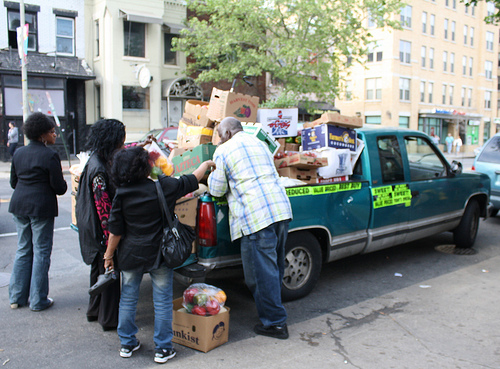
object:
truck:
[67, 123, 491, 304]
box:
[203, 87, 260, 123]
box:
[254, 107, 299, 139]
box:
[302, 111, 364, 131]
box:
[297, 120, 359, 155]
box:
[272, 150, 327, 169]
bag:
[180, 281, 227, 316]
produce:
[189, 293, 209, 309]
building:
[186, 0, 267, 105]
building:
[0, 0, 97, 161]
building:
[266, 0, 498, 160]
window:
[404, 17, 411, 29]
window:
[398, 50, 405, 62]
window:
[397, 75, 405, 90]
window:
[374, 89, 383, 101]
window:
[427, 79, 435, 94]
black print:
[284, 186, 309, 198]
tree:
[170, 0, 406, 114]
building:
[295, 99, 341, 122]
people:
[451, 134, 463, 156]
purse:
[149, 175, 194, 268]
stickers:
[309, 180, 361, 195]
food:
[199, 125, 213, 139]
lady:
[6, 110, 68, 314]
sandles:
[86, 268, 118, 294]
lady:
[101, 144, 216, 365]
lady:
[73, 114, 125, 331]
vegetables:
[158, 161, 176, 177]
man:
[206, 115, 296, 342]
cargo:
[168, 142, 220, 178]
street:
[0, 151, 499, 369]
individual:
[4, 119, 19, 158]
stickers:
[390, 182, 412, 209]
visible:
[182, 280, 230, 318]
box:
[157, 297, 232, 355]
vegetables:
[206, 299, 220, 316]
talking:
[0, 108, 296, 369]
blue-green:
[370, 202, 399, 216]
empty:
[104, 85, 348, 208]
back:
[163, 190, 235, 285]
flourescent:
[389, 183, 412, 208]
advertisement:
[367, 184, 395, 211]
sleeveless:
[72, 154, 117, 266]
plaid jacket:
[202, 130, 294, 242]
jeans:
[239, 225, 290, 329]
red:
[202, 303, 222, 313]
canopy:
[155, 74, 204, 102]